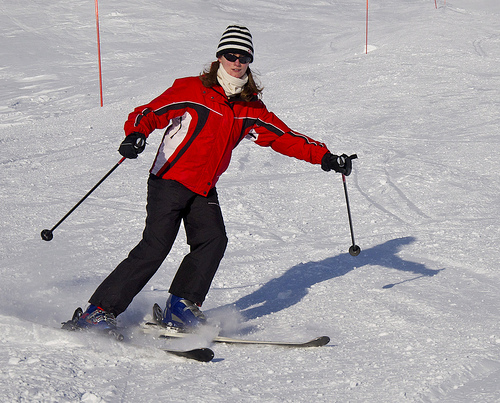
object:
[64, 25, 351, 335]
woman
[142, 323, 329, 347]
skiis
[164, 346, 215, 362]
skiis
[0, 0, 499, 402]
ground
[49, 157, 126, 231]
pole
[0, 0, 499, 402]
surface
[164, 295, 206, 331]
ski shoes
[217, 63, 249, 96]
cowl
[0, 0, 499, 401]
snow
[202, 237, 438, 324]
shadow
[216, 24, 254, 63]
hat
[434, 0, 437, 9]
marker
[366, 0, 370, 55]
marker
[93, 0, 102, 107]
marker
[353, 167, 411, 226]
trail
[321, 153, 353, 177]
gloves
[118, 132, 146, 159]
gloves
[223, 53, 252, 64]
sunglasses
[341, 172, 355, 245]
pole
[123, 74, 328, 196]
jacket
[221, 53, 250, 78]
face